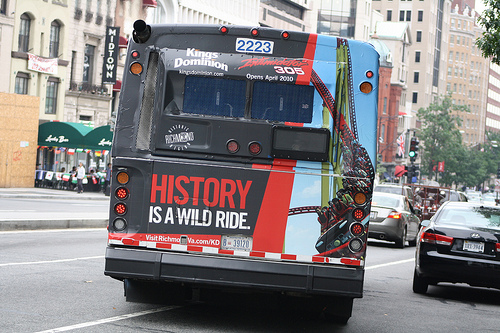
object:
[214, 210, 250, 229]
word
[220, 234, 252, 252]
license plate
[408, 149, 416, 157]
light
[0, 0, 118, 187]
building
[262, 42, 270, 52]
number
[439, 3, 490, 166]
building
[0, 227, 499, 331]
road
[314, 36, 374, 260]
roller coaster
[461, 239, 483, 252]
license plate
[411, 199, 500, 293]
car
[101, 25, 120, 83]
sign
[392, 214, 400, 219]
tail light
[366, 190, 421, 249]
car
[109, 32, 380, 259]
advertisement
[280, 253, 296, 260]
reflector strip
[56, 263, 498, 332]
road side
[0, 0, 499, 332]
traffic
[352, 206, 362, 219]
brake light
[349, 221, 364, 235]
brake light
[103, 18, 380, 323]
bus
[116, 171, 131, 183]
reflector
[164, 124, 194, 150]
logo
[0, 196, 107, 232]
median